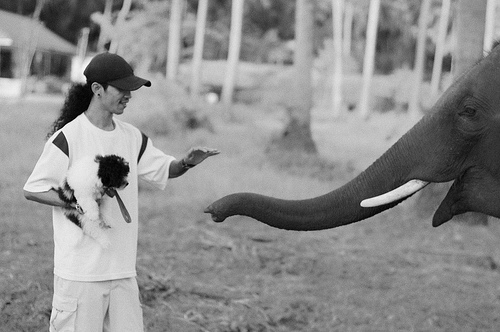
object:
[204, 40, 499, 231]
elephant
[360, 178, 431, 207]
horn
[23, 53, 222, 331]
female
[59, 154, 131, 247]
doll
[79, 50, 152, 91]
hat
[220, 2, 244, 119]
tree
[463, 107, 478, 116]
left eye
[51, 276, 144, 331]
pants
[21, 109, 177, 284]
shirt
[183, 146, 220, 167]
left hand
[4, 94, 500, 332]
yard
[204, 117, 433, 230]
trunk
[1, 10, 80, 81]
building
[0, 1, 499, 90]
distance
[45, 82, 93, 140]
hair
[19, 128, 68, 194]
short sleeves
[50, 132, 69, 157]
stripe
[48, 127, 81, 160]
shoulder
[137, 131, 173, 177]
arm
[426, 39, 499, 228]
head